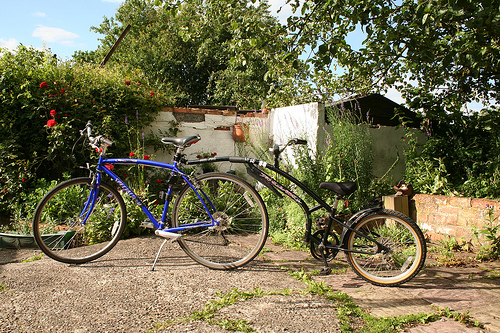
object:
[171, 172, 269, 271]
wheel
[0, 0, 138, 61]
sky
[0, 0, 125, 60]
clouds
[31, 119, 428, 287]
bicycle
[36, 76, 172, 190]
flowers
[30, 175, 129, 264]
tire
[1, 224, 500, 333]
ground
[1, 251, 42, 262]
grass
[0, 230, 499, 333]
cracks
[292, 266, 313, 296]
grass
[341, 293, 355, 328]
grass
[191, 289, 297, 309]
grass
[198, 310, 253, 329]
grass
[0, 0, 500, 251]
trees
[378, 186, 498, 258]
wall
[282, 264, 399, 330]
grass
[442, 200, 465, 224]
bricks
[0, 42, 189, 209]
bush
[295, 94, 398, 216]
bushes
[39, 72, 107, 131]
roses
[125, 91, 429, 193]
wall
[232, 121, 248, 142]
pot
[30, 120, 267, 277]
skateboard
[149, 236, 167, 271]
kick stand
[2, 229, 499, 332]
cement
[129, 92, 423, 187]
building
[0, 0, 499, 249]
foliage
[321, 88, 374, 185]
flowers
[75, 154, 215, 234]
body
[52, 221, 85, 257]
spokes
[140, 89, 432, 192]
house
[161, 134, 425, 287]
seat extension